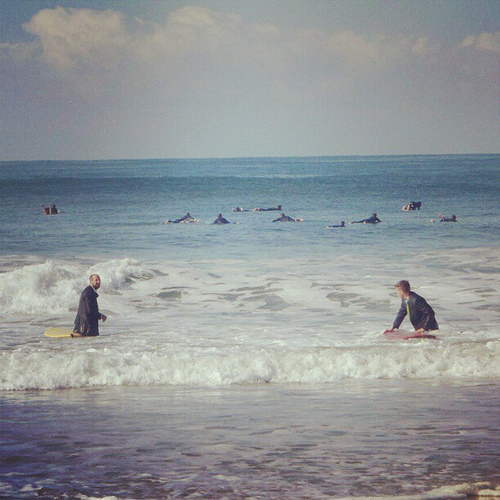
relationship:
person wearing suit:
[381, 277, 438, 337] [384, 291, 438, 338]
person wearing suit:
[381, 277, 438, 337] [387, 289, 444, 340]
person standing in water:
[381, 277, 438, 337] [2, 154, 492, 496]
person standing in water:
[69, 274, 109, 338] [2, 154, 492, 496]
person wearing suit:
[69, 274, 109, 338] [74, 284, 102, 342]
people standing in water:
[33, 195, 467, 231] [2, 154, 492, 496]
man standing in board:
[75, 270, 105, 340] [37, 321, 80, 343]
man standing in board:
[385, 275, 433, 338] [376, 325, 442, 345]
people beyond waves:
[33, 195, 467, 231] [1, 245, 494, 392]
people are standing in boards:
[33, 195, 467, 231] [42, 206, 452, 234]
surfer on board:
[74, 272, 113, 342] [33, 321, 113, 343]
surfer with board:
[383, 273, 444, 332] [386, 331, 432, 342]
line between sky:
[4, 154, 230, 166] [3, 7, 253, 120]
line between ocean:
[4, 154, 230, 166] [96, 167, 330, 273]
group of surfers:
[170, 209, 381, 238] [37, 197, 467, 231]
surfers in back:
[37, 197, 467, 231] [3, 159, 498, 268]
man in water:
[385, 275, 433, 338] [0, 180, 500, 498]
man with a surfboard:
[385, 275, 433, 338] [381, 329, 437, 345]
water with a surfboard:
[0, 180, 500, 498] [381, 329, 437, 345]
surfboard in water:
[381, 329, 437, 345] [0, 180, 500, 498]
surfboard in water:
[385, 329, 436, 345] [306, 392, 459, 467]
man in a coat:
[75, 270, 105, 340] [72, 292, 98, 328]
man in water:
[75, 270, 105, 340] [73, 386, 315, 469]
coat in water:
[72, 292, 98, 328] [73, 386, 315, 469]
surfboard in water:
[43, 325, 76, 342] [186, 394, 353, 472]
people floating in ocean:
[33, 195, 467, 231] [0, 161, 494, 497]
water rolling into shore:
[0, 180, 500, 498] [15, 460, 306, 497]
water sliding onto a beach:
[0, 180, 500, 498] [4, 467, 286, 497]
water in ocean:
[149, 261, 305, 376] [0, 161, 494, 497]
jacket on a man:
[400, 299, 430, 320] [383, 273, 436, 333]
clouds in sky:
[0, 13, 488, 101] [1, 0, 497, 156]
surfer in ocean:
[383, 273, 444, 332] [0, 161, 494, 497]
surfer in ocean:
[74, 272, 113, 342] [0, 161, 494, 497]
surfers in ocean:
[37, 197, 467, 231] [0, 161, 494, 497]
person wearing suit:
[69, 274, 109, 338] [78, 289, 104, 334]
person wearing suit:
[69, 274, 109, 338] [71, 289, 101, 339]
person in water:
[69, 274, 109, 338] [2, 154, 492, 496]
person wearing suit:
[381, 277, 438, 337] [388, 298, 436, 340]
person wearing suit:
[381, 277, 438, 337] [385, 300, 443, 341]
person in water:
[381, 277, 438, 337] [2, 154, 492, 496]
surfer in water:
[74, 272, 113, 342] [2, 154, 492, 496]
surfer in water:
[383, 273, 444, 332] [2, 154, 492, 496]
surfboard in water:
[381, 329, 437, 345] [2, 154, 492, 496]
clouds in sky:
[0, 13, 488, 101] [2, 14, 493, 161]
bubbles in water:
[271, 282, 312, 309] [2, 154, 492, 496]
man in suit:
[75, 270, 105, 340] [72, 285, 111, 334]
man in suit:
[385, 275, 433, 338] [377, 288, 442, 332]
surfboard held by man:
[43, 325, 76, 342] [37, 273, 139, 339]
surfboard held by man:
[381, 329, 437, 345] [365, 272, 442, 336]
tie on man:
[386, 294, 424, 336] [358, 268, 444, 325]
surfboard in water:
[43, 325, 76, 342] [15, 348, 142, 416]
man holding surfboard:
[385, 275, 433, 338] [370, 314, 438, 363]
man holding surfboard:
[75, 270, 105, 340] [42, 314, 72, 359]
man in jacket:
[75, 270, 105, 340] [72, 279, 106, 336]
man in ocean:
[385, 275, 433, 338] [297, 309, 369, 386]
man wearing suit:
[385, 275, 433, 338] [392, 309, 437, 331]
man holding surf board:
[385, 275, 433, 338] [378, 329, 436, 339]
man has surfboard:
[385, 275, 433, 338] [378, 329, 438, 342]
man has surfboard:
[75, 270, 105, 340] [43, 325, 79, 338]